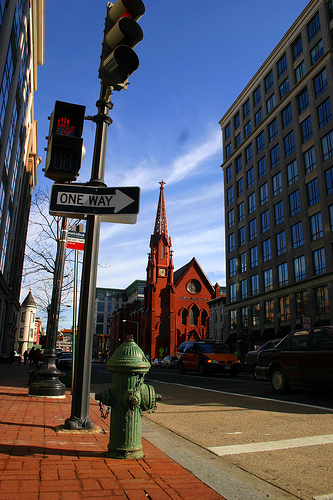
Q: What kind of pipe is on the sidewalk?
A: Water.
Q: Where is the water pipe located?
A: Sidewalk.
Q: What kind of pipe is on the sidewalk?
A: Water.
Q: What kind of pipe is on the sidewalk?
A: Water.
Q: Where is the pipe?
A: Sidewalk.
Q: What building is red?
A: Church.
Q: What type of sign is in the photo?
A: One way.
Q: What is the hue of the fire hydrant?
A: Green.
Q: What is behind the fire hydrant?
A: Church.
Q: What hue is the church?
A: Red.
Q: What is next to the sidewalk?
A: Street.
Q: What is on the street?
A: Cars.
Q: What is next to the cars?
A: Building.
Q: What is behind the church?
A: Sky.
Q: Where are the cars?
A: On the street.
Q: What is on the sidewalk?
A: Hydrant.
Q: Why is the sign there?
A: Warning.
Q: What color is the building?
A: Red.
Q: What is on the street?
A: Cars.